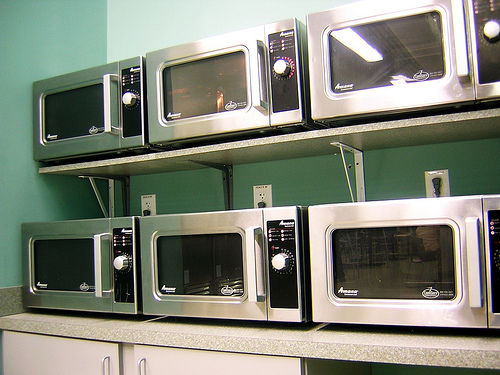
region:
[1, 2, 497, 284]
the wall is green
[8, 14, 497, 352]
toaster ovens all next to each other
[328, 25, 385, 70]
light reflecting on ove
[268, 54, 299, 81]
red numbers on ove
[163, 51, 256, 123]
light on in oven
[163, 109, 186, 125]
white letters on oven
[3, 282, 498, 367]
the counter is gray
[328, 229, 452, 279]
reflection in the oven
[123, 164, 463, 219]
cords plugged into the wall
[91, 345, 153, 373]
cabinet handles are silver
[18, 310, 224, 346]
counter top with microwave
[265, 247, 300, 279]
knob on the microwave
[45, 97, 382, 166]
shelf with microwave ovens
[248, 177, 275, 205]
electrical outlet behind microwave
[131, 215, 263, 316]
microwave door to electronic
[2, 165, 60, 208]
green paint on the wall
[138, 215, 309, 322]
microwave that is plugged in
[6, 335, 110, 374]
cabinets with white paint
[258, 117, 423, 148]
shelf holding three microwaves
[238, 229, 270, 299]
door handle to microwave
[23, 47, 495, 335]
Six microwaves on the counter.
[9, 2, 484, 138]
Three microwaves on the shelf.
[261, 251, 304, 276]
Silver knob on the microwave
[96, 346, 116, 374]
Handle on the cabinet.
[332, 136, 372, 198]
Latches under the shelf.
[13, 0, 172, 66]
The wall is green.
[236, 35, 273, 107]
Door handle of the microwave.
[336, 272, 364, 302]
White writing on the microwave.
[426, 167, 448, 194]
Black cord in the electrical outlet.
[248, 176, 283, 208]
Electrical outlet on the wall.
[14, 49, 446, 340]
a bunch of silver microwaves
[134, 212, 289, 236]
the steel part of a microwave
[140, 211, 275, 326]
the door of a microwave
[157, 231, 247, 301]
the window of a microwave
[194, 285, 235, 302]
the tray of a microwave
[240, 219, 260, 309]
the handle of a microwave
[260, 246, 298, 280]
the knob of a microwave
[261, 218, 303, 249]
the buttons of a microwave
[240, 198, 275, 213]
the plug of a microwave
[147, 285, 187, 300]
the logo of a microwave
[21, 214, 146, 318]
a silver microwave oven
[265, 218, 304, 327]
the control knob and panel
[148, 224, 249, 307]
window on front of toaster oven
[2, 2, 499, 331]
six ovens on shelves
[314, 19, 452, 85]
reflection of light in appliance window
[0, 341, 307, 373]
cabinet doors under counter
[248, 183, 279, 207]
electrical outlet on wall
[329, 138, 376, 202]
metal support under shelf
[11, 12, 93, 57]
aqua painted wall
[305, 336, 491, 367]
grey formica counter